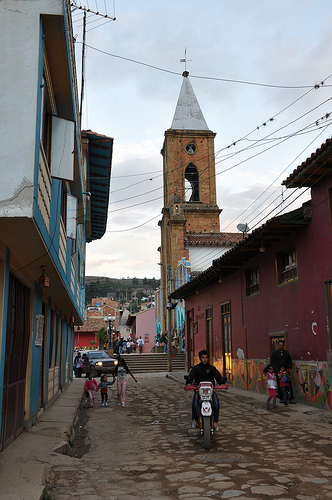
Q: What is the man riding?
A: A motorcycle.